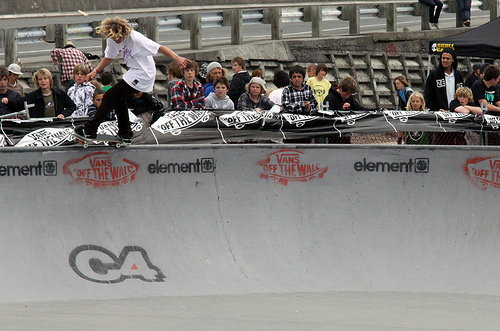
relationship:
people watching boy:
[2, 40, 491, 135] [73, 17, 193, 144]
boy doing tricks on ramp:
[73, 17, 193, 144] [5, 135, 497, 318]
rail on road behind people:
[2, 4, 499, 49] [0, 18, 497, 115]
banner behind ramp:
[5, 105, 498, 148] [0, 145, 498, 329]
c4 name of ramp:
[66, 242, 164, 282] [0, 145, 498, 329]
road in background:
[8, 0, 493, 60] [1, 1, 498, 72]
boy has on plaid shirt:
[170, 59, 206, 110] [170, 78, 206, 109]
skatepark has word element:
[9, 32, 499, 282] [344, 151, 433, 179]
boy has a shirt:
[80, 17, 194, 142] [103, 29, 163, 94]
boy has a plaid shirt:
[167, 62, 205, 109] [280, 84, 319, 115]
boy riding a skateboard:
[73, 17, 193, 144] [59, 116, 125, 151]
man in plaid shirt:
[50, 41, 94, 94] [50, 47, 94, 82]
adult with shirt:
[418, 40, 466, 110] [444, 70, 457, 101]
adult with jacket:
[418, 40, 466, 110] [424, 65, 466, 111]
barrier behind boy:
[198, 42, 496, 106] [73, 17, 193, 144]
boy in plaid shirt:
[281, 65, 321, 117] [167, 77, 206, 108]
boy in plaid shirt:
[281, 65, 321, 117] [279, 85, 317, 112]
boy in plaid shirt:
[281, 65, 321, 117] [48, 46, 86, 65]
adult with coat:
[424, 47, 466, 111] [422, 61, 472, 113]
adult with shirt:
[424, 47, 466, 111] [443, 73, 455, 106]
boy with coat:
[73, 17, 193, 144] [422, 61, 472, 113]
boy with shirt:
[73, 17, 193, 144] [443, 73, 455, 106]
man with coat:
[25, 65, 67, 128] [422, 61, 472, 113]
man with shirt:
[25, 65, 67, 128] [443, 73, 455, 106]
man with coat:
[46, 37, 108, 101] [422, 61, 472, 113]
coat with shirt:
[422, 61, 472, 113] [443, 73, 455, 106]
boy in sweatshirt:
[73, 17, 193, 144] [204, 92, 237, 112]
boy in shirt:
[304, 62, 332, 111] [308, 76, 332, 111]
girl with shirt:
[399, 86, 436, 137] [401, 105, 434, 148]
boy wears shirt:
[170, 59, 206, 110] [47, 44, 98, 83]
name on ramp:
[141, 151, 223, 180] [0, 135, 463, 304]